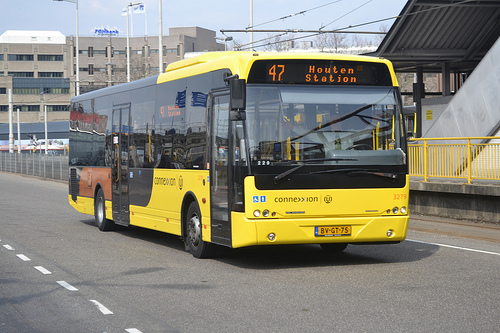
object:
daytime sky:
[3, 0, 400, 48]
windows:
[87, 47, 95, 58]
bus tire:
[186, 202, 215, 259]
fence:
[408, 136, 500, 185]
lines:
[7, 245, 108, 330]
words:
[269, 65, 357, 82]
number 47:
[269, 64, 285, 81]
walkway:
[409, 166, 499, 186]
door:
[206, 87, 236, 248]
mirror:
[229, 79, 246, 110]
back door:
[111, 101, 130, 227]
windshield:
[243, 85, 408, 173]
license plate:
[315, 225, 352, 236]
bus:
[68, 51, 410, 259]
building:
[0, 21, 240, 155]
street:
[4, 170, 500, 333]